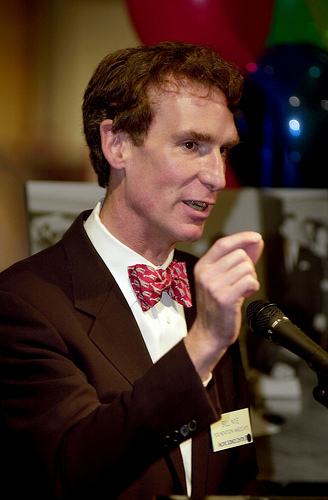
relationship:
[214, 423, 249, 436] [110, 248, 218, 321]
word on tag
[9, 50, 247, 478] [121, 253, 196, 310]
man wearing tie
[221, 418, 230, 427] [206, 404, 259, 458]
word on tag